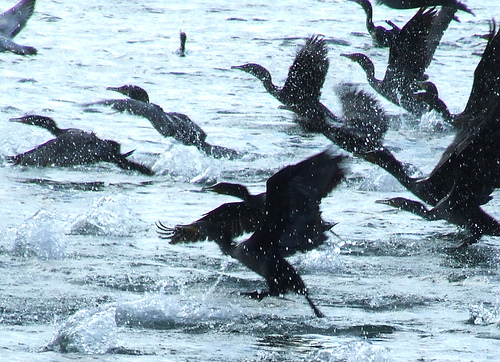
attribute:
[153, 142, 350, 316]
bird — black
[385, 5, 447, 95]
wings — extended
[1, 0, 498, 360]
scene — grey, rainy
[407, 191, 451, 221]
neck — bent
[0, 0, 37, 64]
bird — flying, black, wet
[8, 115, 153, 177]
bird — flying, black, wet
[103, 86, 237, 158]
bird — flying, black, wet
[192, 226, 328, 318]
bird — flying, black, wet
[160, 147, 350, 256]
bird — flying, black, wet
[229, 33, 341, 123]
bird — flying, black, wet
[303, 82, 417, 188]
bird — flying, black, wet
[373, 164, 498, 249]
bird — flying, black, wet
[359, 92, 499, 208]
bird — flying, black, wet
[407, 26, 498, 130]
bird — flying, black, wet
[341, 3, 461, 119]
bird — flying, black, wet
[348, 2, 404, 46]
bird — flying, black, wet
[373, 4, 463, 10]
bird — flying, black, wet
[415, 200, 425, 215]
droplets — water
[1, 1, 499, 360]
water — turquoise, silver, blue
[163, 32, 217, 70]
duck — white 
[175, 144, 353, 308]
sea birds — black